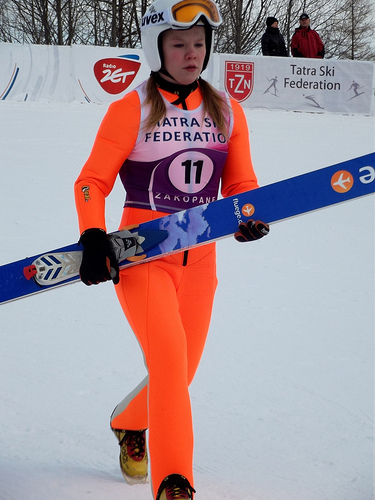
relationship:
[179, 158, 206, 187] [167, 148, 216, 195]
"11" inside circle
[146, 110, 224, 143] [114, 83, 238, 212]
letters across shirt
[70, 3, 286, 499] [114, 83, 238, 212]
person wearing shirt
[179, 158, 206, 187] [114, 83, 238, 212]
"11" across shirt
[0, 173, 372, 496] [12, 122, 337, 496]
ground covered ground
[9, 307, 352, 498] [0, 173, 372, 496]
ground covered in ground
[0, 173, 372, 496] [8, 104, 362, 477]
ground covered in ground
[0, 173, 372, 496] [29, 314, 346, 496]
ground covered in ground